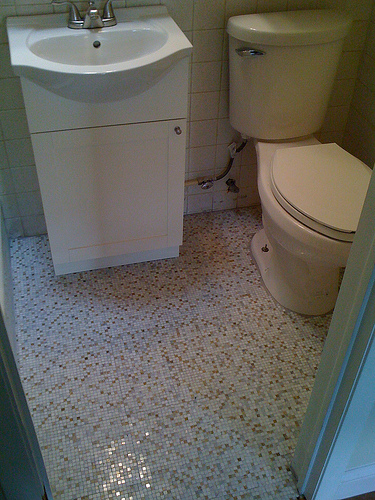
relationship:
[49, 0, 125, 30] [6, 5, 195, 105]
faucet on sink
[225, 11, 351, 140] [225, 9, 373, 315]
tank of toilet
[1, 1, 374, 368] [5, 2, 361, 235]
tile on wall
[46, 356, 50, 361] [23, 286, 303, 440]
tile on floor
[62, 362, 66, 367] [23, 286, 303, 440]
tile on floor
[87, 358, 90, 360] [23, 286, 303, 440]
tile on floor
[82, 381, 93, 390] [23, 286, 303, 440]
tile on floor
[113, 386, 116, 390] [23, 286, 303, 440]
tile on floor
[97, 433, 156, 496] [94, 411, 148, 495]
light on tiles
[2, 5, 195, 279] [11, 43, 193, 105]
sink has curved edge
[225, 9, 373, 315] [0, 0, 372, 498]
toilet in bathroom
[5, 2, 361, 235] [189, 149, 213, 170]
wall has tile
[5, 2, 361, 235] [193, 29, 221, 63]
wall has tile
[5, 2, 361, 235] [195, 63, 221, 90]
wall has tile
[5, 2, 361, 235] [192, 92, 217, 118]
wall has tile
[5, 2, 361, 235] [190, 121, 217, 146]
wall has tile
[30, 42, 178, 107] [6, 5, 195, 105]
lip on sink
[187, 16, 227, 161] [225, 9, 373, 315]
tile behind toilet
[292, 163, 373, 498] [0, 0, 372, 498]
doorway of bathroom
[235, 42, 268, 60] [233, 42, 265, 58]
handle on toilet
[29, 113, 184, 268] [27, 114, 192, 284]
door on cabinet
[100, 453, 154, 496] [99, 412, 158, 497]
light reflection on tile